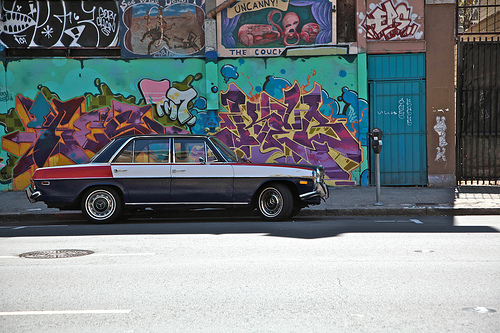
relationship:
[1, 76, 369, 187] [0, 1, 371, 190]
graffiti on wall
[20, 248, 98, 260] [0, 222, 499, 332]
cover in road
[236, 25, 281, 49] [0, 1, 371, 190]
couch on wall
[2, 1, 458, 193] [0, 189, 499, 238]
building has shadow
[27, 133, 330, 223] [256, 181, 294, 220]
car has wheel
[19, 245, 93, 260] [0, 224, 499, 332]
whole in street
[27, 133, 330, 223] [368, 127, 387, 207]
car near meter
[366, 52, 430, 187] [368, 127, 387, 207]
door behind meter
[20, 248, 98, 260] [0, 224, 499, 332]
cover on street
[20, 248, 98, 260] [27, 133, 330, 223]
cover near car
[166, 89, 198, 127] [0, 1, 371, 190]
number on wall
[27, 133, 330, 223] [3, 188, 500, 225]
car next to sidewalk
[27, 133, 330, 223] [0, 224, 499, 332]
car on street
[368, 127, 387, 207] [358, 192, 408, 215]
meter on curb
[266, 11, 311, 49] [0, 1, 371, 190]
octopus on wall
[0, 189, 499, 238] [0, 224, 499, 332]
shadow on street